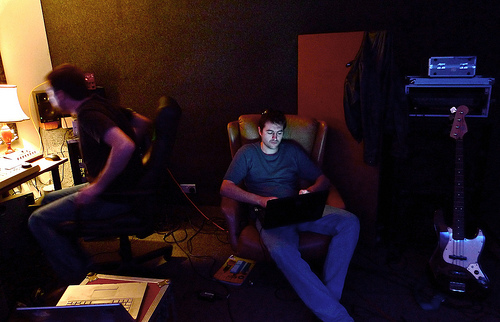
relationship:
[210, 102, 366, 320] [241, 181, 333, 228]
man on laptop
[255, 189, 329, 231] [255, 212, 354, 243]
lap on lap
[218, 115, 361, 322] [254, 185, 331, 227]
man looking at laptop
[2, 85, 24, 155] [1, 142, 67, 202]
lamp on table